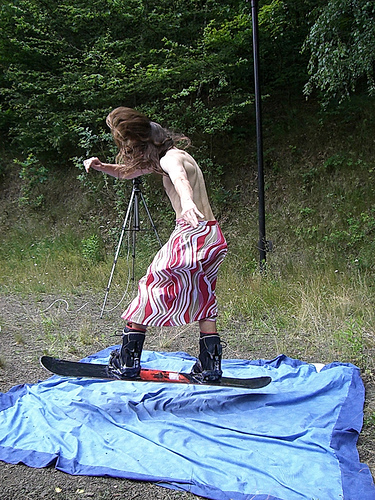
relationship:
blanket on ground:
[0, 342, 373, 498] [240, 81, 294, 134]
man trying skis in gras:
[84, 105, 227, 384] [0, 132, 375, 360]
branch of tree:
[192, 102, 234, 142] [5, 1, 264, 200]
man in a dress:
[84, 105, 227, 384] [119, 217, 227, 325]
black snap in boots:
[118, 338, 144, 374] [98, 328, 239, 392]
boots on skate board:
[98, 328, 239, 392] [39, 355, 271, 389]